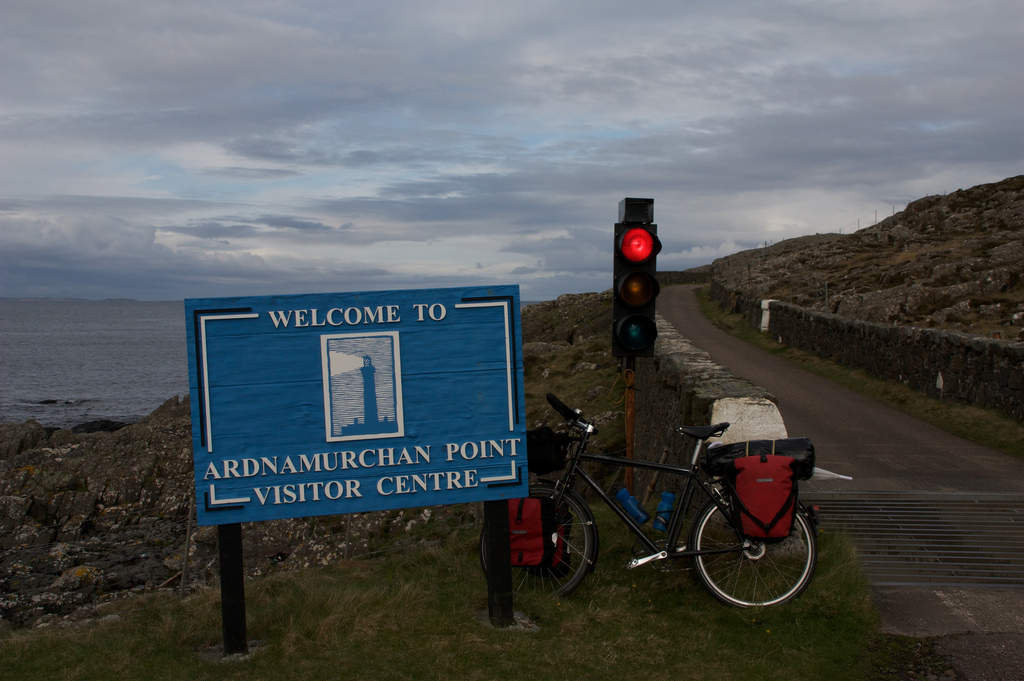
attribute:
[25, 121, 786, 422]
sky — grey, cloudy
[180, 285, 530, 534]
sign — blue, white and black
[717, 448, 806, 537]
bag — red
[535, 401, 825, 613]
bike — black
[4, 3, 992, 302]
sky — blue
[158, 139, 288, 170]
cloud — white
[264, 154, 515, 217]
cloud — white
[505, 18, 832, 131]
cloud — white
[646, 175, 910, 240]
cloud — white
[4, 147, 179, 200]
cloud — white